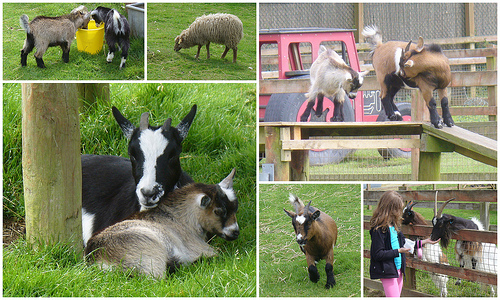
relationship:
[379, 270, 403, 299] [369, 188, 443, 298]
pants on girl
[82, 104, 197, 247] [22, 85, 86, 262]
animal on post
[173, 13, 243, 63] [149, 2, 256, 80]
goats eat grass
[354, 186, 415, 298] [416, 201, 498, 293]
girl feeds goat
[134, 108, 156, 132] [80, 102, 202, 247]
horn on goat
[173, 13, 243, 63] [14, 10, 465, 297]
goats in photo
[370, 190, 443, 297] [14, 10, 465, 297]
girl in photo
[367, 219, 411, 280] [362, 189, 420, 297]
black coat on girl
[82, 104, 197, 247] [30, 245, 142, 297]
animal in grass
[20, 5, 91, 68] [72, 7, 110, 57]
dog drinking water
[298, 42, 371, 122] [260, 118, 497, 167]
goat on railing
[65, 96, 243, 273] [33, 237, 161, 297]
goats in grass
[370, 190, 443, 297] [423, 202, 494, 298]
girl feeding goat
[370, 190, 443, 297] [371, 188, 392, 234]
girl has hair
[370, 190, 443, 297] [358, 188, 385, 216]
girl has hair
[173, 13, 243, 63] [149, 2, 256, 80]
goats in grass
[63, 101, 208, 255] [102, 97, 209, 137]
goat has horns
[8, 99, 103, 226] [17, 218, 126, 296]
pole in ground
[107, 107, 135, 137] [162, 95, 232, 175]
black ear on right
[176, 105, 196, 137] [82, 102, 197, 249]
ear on animal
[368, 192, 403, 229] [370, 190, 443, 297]
hair on girl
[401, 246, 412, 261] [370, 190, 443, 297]
hand on girl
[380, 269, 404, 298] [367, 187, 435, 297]
pants on girl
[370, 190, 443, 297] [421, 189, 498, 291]
girl feeding goat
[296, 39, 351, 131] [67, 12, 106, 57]
goat drinking from bucket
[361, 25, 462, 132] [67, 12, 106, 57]
goat drinking from bucket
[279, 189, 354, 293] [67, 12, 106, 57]
goat drinking from bucket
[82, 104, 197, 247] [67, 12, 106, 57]
animal drinking from bucket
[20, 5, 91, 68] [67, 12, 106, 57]
dog drinking from bucket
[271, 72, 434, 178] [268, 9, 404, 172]
tires are in background